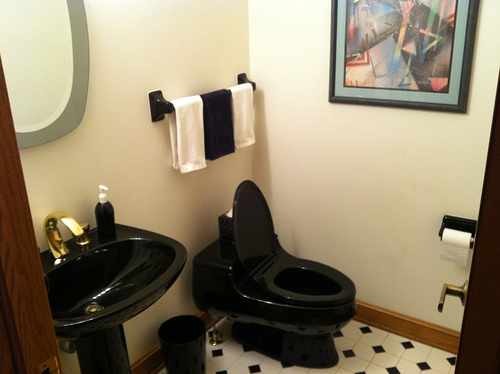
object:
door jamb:
[0, 60, 62, 371]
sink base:
[75, 325, 131, 372]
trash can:
[150, 311, 208, 372]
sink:
[40, 205, 186, 373]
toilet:
[188, 177, 360, 368]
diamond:
[375, 345, 385, 354]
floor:
[159, 315, 457, 371]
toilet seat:
[255, 255, 363, 314]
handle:
[429, 281, 468, 314]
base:
[131, 300, 462, 371]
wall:
[0, 0, 498, 371]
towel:
[198, 86, 237, 160]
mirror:
[0, 0, 90, 148]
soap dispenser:
[89, 182, 119, 242]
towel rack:
[146, 73, 264, 126]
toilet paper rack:
[433, 208, 477, 246]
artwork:
[325, 0, 482, 113]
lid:
[228, 178, 280, 273]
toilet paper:
[432, 227, 472, 261]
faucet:
[41, 207, 97, 267]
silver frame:
[16, 0, 89, 147]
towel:
[229, 83, 258, 150]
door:
[454, 73, 499, 371]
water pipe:
[204, 311, 224, 345]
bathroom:
[0, 3, 499, 372]